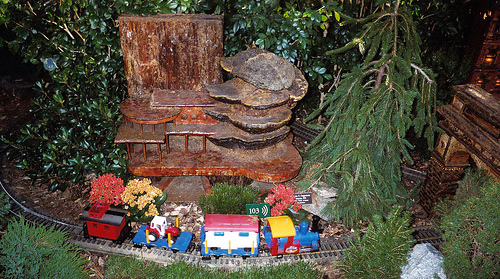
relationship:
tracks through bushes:
[0, 105, 459, 272] [1, 2, 498, 278]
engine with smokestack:
[262, 214, 320, 256] [311, 215, 319, 233]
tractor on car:
[145, 216, 180, 244] [132, 222, 193, 252]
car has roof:
[200, 213, 260, 260] [204, 213, 257, 230]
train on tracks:
[80, 204, 322, 258] [0, 105, 459, 272]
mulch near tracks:
[0, 77, 89, 226] [0, 105, 459, 272]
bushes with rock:
[333, 166, 500, 278] [399, 241, 448, 278]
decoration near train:
[112, 12, 308, 200] [80, 204, 322, 258]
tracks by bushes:
[0, 105, 459, 272] [1, 2, 498, 278]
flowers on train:
[89, 173, 164, 217] [80, 204, 322, 258]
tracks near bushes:
[0, 105, 459, 272] [1, 2, 498, 278]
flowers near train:
[89, 173, 164, 217] [80, 204, 322, 258]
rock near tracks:
[399, 241, 448, 278] [0, 105, 459, 272]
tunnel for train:
[417, 83, 500, 218] [80, 204, 322, 258]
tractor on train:
[145, 216, 180, 244] [80, 204, 322, 258]